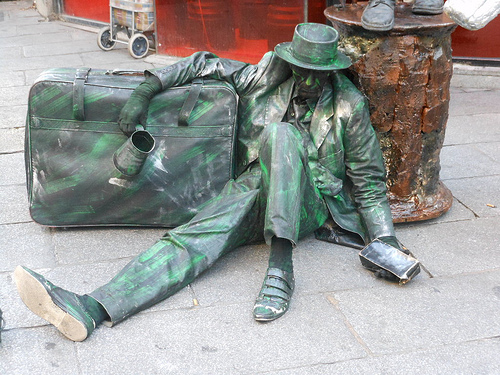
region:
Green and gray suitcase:
[21, 63, 241, 229]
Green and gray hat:
[269, 17, 352, 72]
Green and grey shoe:
[248, 268, 297, 324]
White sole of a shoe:
[9, 264, 94, 346]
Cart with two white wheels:
[96, 0, 158, 58]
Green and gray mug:
[107, 125, 157, 182]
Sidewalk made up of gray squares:
[11, 26, 79, 61]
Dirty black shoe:
[359, 0, 397, 32]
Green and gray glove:
[113, 69, 165, 139]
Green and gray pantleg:
[254, 120, 308, 247]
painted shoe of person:
[251, 265, 295, 321]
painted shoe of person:
[10, 271, 95, 338]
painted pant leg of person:
[92, 183, 257, 323]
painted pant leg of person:
[262, 135, 326, 240]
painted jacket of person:
[152, 50, 400, 240]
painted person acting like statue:
[22, 23, 422, 330]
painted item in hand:
[362, 235, 417, 283]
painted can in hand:
[112, 129, 157, 177]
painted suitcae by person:
[29, 70, 236, 219]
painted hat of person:
[270, 23, 355, 71]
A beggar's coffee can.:
[112, 131, 157, 181]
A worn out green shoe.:
[256, 265, 295, 332]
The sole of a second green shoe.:
[3, 268, 95, 347]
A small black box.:
[349, 234, 421, 290]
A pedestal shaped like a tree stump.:
[368, 52, 457, 224]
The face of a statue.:
[288, 65, 326, 98]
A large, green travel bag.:
[19, 68, 239, 235]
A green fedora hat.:
[267, 18, 352, 78]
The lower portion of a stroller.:
[95, 3, 162, 57]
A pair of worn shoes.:
[342, 2, 445, 28]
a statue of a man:
[1, 18, 428, 335]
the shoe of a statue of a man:
[251, 260, 305, 324]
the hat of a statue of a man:
[269, 20, 360, 74]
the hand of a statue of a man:
[116, 88, 153, 131]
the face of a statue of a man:
[288, 61, 328, 101]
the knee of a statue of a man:
[260, 122, 305, 144]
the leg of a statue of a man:
[103, 188, 255, 346]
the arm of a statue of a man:
[337, 95, 404, 237]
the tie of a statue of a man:
[287, 98, 316, 132]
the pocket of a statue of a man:
[316, 149, 350, 189]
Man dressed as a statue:
[22, 42, 476, 343]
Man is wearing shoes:
[232, 250, 307, 340]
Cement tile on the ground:
[204, 290, 255, 355]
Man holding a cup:
[97, 78, 180, 183]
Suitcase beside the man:
[12, 50, 302, 272]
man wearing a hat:
[273, 19, 378, 101]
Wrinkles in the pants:
[140, 206, 232, 266]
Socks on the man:
[257, 230, 309, 275]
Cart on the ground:
[92, 9, 202, 74]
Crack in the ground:
[321, 288, 373, 369]